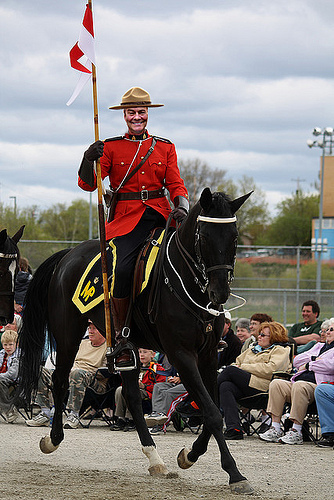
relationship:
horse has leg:
[19, 179, 273, 480] [176, 353, 263, 485]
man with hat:
[75, 45, 196, 238] [100, 81, 145, 107]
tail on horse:
[14, 257, 58, 384] [19, 179, 273, 480]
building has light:
[306, 115, 332, 268] [289, 66, 329, 176]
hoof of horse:
[162, 433, 264, 489] [19, 179, 273, 480]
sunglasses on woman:
[262, 327, 294, 349] [147, 304, 301, 468]